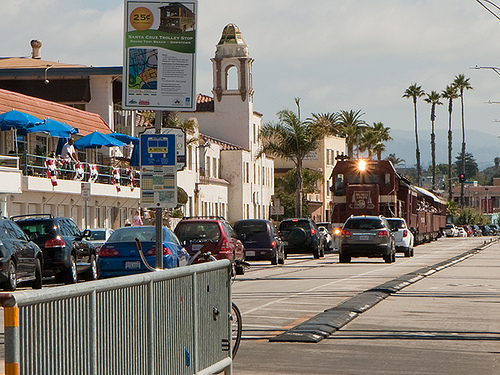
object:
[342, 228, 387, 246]
back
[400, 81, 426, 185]
palm trees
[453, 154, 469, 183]
traffic light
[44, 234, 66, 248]
rear light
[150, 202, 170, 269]
post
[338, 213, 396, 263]
car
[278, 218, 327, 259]
car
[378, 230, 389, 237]
light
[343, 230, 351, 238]
light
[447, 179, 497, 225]
building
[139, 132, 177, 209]
bus top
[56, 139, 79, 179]
people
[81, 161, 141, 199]
balcony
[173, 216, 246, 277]
car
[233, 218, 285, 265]
car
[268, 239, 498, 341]
road divider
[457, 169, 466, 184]
traffic signal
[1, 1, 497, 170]
sky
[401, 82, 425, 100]
leaves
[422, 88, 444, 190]
palm trees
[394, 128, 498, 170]
mountains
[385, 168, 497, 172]
horizon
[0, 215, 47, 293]
cars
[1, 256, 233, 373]
rails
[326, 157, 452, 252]
commuter trolley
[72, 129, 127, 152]
umbrellas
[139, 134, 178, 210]
signs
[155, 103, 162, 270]
pole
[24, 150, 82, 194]
balcony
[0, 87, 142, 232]
building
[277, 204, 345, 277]
cars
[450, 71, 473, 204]
trees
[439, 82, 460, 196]
trees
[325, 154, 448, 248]
car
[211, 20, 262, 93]
dome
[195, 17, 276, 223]
building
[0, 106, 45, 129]
umbrellas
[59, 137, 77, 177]
man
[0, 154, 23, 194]
balcony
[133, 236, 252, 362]
bicycle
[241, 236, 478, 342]
lines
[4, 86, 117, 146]
roof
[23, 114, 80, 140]
umbrellas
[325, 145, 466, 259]
train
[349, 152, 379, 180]
light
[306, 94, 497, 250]
background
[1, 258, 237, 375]
barrier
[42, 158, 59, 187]
banners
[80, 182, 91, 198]
sign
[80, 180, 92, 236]
pole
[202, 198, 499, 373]
road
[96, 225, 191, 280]
car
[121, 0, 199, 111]
sign